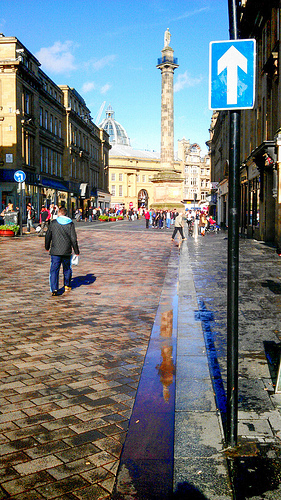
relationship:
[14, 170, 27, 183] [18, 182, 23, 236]
round sign on post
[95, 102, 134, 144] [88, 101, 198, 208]
glass dome on church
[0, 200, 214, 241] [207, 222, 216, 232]
many people in a wheelchair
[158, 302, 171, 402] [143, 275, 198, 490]
reflection in a puddle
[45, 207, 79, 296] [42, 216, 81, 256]
man in jacket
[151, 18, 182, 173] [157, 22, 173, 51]
tower with sculpture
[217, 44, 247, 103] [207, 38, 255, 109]
arrow on sign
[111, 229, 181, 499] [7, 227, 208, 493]
puddle in street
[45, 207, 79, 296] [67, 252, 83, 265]
man carrying bag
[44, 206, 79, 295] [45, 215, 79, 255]
man wearing jacket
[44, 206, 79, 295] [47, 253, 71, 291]
man wearing jeans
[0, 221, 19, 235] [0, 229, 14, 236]
plants in planter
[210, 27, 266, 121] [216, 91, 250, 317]
sign on post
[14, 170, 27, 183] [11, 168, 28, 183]
round sign on round sign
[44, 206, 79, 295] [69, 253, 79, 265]
man carrying bag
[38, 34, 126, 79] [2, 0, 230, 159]
clouds in sky